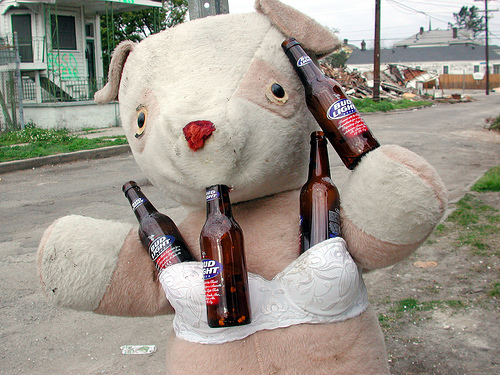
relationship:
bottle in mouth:
[200, 185, 253, 328] [206, 181, 232, 194]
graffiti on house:
[44, 50, 80, 84] [0, 1, 164, 135]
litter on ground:
[119, 343, 157, 354] [0, 88, 499, 374]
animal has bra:
[35, 0, 447, 374] [157, 236, 366, 344]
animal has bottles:
[35, 0, 447, 374] [122, 35, 380, 329]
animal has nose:
[35, 0, 447, 374] [182, 120, 217, 151]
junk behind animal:
[318, 63, 442, 100] [35, 0, 447, 374]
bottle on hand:
[282, 37, 380, 170] [340, 145, 447, 268]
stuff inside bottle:
[205, 266, 250, 325] [200, 185, 253, 328]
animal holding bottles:
[35, 0, 447, 374] [122, 35, 380, 329]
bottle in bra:
[123, 179, 196, 273] [157, 236, 366, 344]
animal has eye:
[35, 0, 447, 374] [135, 108, 147, 134]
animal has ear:
[35, 0, 447, 374] [93, 40, 132, 105]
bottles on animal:
[122, 35, 380, 329] [35, 0, 447, 374]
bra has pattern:
[157, 236, 366, 344] [157, 236, 372, 344]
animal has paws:
[35, 0, 447, 374] [34, 143, 447, 318]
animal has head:
[35, 0, 447, 374] [93, 0, 339, 212]